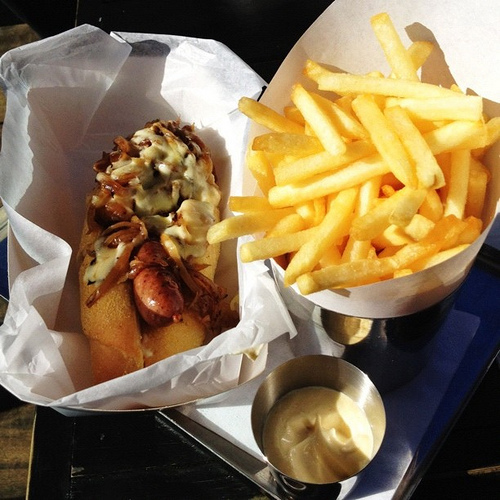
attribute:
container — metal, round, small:
[249, 355, 388, 499]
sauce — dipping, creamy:
[263, 386, 376, 484]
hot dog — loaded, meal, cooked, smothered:
[133, 267, 184, 326]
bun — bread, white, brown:
[79, 205, 220, 388]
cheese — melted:
[83, 119, 221, 286]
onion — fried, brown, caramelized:
[86, 116, 227, 317]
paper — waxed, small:
[0, 22, 300, 409]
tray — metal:
[154, 213, 500, 499]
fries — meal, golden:
[206, 11, 500, 298]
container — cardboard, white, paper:
[243, 0, 500, 318]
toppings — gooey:
[79, 118, 230, 322]